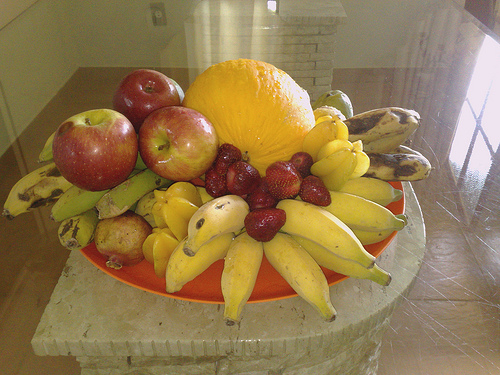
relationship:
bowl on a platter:
[77, 181, 403, 306] [58, 173, 409, 303]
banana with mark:
[181, 192, 246, 257] [194, 216, 206, 229]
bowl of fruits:
[77, 181, 403, 306] [1, 54, 436, 333]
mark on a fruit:
[344, 111, 382, 135] [341, 108, 418, 145]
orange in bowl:
[189, 83, 312, 193] [77, 36, 411, 341]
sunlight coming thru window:
[457, 47, 499, 185] [445, 18, 498, 232]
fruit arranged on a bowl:
[121, 54, 374, 279] [77, 181, 403, 306]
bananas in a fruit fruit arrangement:
[259, 195, 413, 292] [16, 36, 441, 337]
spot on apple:
[54, 114, 82, 138] [47, 107, 132, 174]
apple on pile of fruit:
[45, 106, 137, 191] [33, 62, 405, 293]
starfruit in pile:
[155, 185, 199, 235] [39, 65, 367, 267]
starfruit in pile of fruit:
[149, 179, 209, 242] [175, 185, 249, 262]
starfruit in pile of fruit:
[137, 223, 181, 276] [214, 223, 266, 328]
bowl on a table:
[77, 181, 403, 306] [77, 318, 342, 363]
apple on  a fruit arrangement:
[51, 108, 138, 192] [53, 77, 384, 300]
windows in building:
[441, 28, 499, 229] [2, 2, 499, 372]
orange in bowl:
[183, 59, 316, 179] [77, 181, 403, 306]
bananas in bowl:
[292, 236, 392, 287] [77, 181, 403, 306]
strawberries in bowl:
[227, 161, 261, 195] [77, 181, 403, 306]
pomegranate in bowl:
[90, 209, 158, 276] [77, 181, 403, 306]